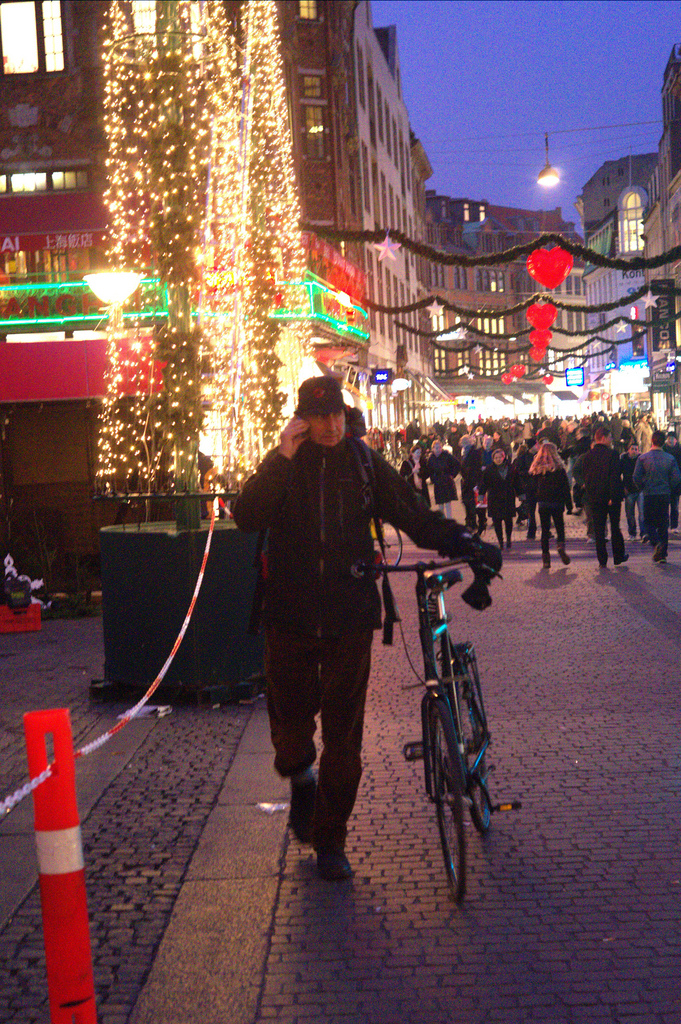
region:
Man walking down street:
[212, 356, 598, 886]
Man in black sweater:
[208, 350, 571, 893]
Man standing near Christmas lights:
[215, 339, 550, 890]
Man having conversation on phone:
[203, 369, 566, 909]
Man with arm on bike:
[207, 358, 580, 891]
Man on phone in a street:
[240, 372, 558, 916]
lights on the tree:
[103, 99, 253, 225]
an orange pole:
[24, 712, 115, 1018]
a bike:
[400, 566, 518, 896]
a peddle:
[493, 795, 520, 815]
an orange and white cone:
[18, 707, 109, 1009]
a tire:
[433, 696, 481, 891]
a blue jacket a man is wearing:
[634, 452, 669, 496]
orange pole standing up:
[16, 710, 116, 1021]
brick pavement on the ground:
[270, 905, 677, 1021]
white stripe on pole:
[22, 822, 99, 881]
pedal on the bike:
[496, 788, 522, 822]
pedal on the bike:
[401, 733, 427, 770]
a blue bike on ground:
[368, 555, 548, 905]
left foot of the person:
[307, 826, 368, 897]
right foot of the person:
[268, 765, 323, 846]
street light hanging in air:
[525, 160, 568, 194]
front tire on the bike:
[409, 698, 482, 911]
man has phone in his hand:
[272, 397, 310, 444]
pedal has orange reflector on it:
[475, 771, 537, 844]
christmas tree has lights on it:
[99, 0, 314, 522]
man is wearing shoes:
[303, 815, 364, 891]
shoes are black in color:
[310, 816, 352, 891]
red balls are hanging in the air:
[518, 289, 569, 342]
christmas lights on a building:
[106, 59, 345, 487]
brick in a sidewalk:
[276, 885, 309, 913]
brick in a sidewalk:
[309, 885, 336, 912]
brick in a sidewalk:
[367, 846, 394, 868]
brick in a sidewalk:
[378, 870, 410, 892]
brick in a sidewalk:
[406, 909, 432, 931]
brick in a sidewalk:
[390, 939, 422, 947]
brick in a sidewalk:
[309, 958, 332, 980]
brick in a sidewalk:
[102, 925, 130, 948]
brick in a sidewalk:
[97, 942, 119, 961]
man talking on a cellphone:
[282, 401, 357, 453]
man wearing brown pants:
[258, 611, 378, 844]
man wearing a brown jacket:
[243, 441, 467, 640]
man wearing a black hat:
[294, 372, 341, 417]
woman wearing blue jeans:
[533, 497, 560, 540]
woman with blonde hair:
[523, 436, 565, 478]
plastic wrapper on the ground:
[254, 792, 287, 822]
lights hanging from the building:
[86, 2, 338, 470]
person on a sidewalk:
[241, 346, 465, 883]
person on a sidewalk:
[526, 443, 579, 569]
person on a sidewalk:
[581, 444, 608, 572]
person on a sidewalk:
[460, 430, 493, 570]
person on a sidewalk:
[399, 436, 418, 477]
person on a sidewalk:
[581, 424, 623, 560]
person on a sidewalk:
[632, 428, 663, 566]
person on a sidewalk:
[488, 421, 519, 479]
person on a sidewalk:
[543, 420, 562, 447]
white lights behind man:
[91, 23, 306, 569]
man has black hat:
[307, 371, 359, 452]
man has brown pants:
[249, 640, 414, 918]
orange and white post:
[11, 675, 59, 1017]